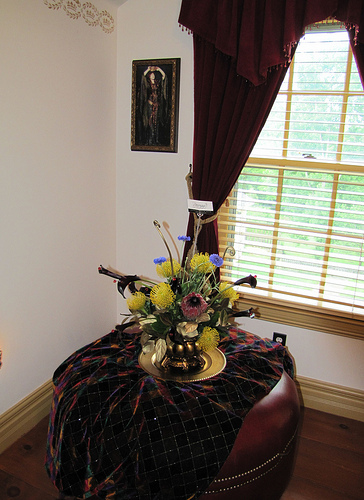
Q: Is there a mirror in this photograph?
A: No, there are no mirrors.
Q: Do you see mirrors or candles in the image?
A: No, there are no mirrors or candles.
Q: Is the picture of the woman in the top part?
A: Yes, the picture is in the top of the image.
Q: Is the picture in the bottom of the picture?
A: No, the picture is in the top of the image.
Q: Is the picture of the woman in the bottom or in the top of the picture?
A: The picture is in the top of the image.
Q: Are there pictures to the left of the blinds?
A: Yes, there is a picture to the left of the blinds.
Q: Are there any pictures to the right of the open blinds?
A: No, the picture is to the left of the blinds.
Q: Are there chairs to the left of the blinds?
A: No, there is a picture to the left of the blinds.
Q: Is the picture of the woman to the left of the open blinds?
A: Yes, the picture is to the left of the blinds.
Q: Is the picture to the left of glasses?
A: No, the picture is to the left of the blinds.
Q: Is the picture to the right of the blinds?
A: No, the picture is to the left of the blinds.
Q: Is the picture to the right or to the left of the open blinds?
A: The picture is to the left of the blinds.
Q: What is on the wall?
A: The picture is on the wall.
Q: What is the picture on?
A: The picture is on the wall.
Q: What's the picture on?
A: The picture is on the wall.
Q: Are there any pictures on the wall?
A: Yes, there is a picture on the wall.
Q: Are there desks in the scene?
A: No, there are no desks.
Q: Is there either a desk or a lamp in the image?
A: No, there are no desks or lamps.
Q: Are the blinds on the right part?
A: Yes, the blinds are on the right of the image.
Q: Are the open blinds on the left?
A: No, the blinds are on the right of the image.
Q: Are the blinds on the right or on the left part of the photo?
A: The blinds are on the right of the image.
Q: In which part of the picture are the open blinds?
A: The blinds are on the right of the image.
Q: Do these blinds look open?
A: Yes, the blinds are open.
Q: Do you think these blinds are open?
A: Yes, the blinds are open.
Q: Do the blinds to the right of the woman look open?
A: Yes, the blinds are open.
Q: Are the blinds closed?
A: No, the blinds are open.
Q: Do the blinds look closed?
A: No, the blinds are open.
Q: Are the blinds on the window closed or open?
A: The blinds are open.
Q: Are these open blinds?
A: Yes, these are open blinds.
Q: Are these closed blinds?
A: No, these are open blinds.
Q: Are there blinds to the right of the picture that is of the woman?
A: Yes, there are blinds to the right of the picture.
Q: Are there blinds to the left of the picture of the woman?
A: No, the blinds are to the right of the picture.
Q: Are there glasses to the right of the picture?
A: No, there are blinds to the right of the picture.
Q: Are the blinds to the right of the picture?
A: Yes, the blinds are to the right of the picture.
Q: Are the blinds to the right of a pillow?
A: No, the blinds are to the right of the picture.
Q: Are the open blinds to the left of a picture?
A: No, the blinds are to the right of a picture.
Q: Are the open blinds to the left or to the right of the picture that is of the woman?
A: The blinds are to the right of the picture.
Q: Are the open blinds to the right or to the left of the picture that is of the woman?
A: The blinds are to the right of the picture.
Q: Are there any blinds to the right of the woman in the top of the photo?
A: Yes, there are blinds to the right of the woman.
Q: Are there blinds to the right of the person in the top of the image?
A: Yes, there are blinds to the right of the woman.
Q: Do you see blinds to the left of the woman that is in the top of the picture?
A: No, the blinds are to the right of the woman.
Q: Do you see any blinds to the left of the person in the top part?
A: No, the blinds are to the right of the woman.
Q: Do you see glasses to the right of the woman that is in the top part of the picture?
A: No, there are blinds to the right of the woman.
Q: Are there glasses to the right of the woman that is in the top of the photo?
A: No, there are blinds to the right of the woman.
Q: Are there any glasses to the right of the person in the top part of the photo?
A: No, there are blinds to the right of the woman.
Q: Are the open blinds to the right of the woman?
A: Yes, the blinds are to the right of the woman.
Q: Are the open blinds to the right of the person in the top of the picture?
A: Yes, the blinds are to the right of the woman.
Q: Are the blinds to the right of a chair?
A: No, the blinds are to the right of the woman.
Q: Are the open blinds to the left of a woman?
A: No, the blinds are to the right of a woman.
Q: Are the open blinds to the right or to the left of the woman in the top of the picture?
A: The blinds are to the right of the woman.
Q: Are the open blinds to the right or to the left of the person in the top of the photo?
A: The blinds are to the right of the woman.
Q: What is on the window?
A: The blinds are on the window.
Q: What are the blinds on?
A: The blinds are on the window.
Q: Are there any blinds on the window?
A: Yes, there are blinds on the window.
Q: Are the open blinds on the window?
A: Yes, the blinds are on the window.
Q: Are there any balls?
A: No, there are no balls.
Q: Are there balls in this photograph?
A: No, there are no balls.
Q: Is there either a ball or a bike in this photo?
A: No, there are no balls or bikes.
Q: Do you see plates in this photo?
A: Yes, there is a plate.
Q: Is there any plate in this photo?
A: Yes, there is a plate.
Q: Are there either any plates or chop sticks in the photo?
A: Yes, there is a plate.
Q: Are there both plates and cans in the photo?
A: No, there is a plate but no cans.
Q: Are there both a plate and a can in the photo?
A: No, there is a plate but no cans.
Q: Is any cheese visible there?
A: No, there is no cheese.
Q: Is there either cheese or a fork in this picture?
A: No, there are no cheese or forks.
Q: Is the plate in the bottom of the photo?
A: Yes, the plate is in the bottom of the image.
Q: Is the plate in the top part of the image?
A: No, the plate is in the bottom of the image.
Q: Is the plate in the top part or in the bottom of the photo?
A: The plate is in the bottom of the image.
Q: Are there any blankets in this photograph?
A: Yes, there is a blanket.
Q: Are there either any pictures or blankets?
A: Yes, there is a blanket.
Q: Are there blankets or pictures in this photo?
A: Yes, there is a blanket.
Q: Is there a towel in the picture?
A: No, there are no towels.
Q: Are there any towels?
A: No, there are no towels.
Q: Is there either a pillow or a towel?
A: No, there are no towels or pillows.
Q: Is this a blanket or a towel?
A: This is a blanket.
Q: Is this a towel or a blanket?
A: This is a blanket.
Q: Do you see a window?
A: Yes, there is a window.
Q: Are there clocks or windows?
A: Yes, there is a window.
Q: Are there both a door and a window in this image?
A: No, there is a window but no doors.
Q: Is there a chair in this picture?
A: No, there are no chairs.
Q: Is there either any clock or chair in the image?
A: No, there are no chairs or clocks.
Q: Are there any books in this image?
A: No, there are no books.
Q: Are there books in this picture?
A: No, there are no books.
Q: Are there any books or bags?
A: No, there are no books or bags.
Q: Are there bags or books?
A: No, there are no books or bags.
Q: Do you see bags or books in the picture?
A: No, there are no books or bags.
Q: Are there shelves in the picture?
A: No, there are no shelves.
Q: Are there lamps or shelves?
A: No, there are no shelves or lamps.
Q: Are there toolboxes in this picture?
A: No, there are no toolboxes.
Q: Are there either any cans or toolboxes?
A: No, there are no toolboxes or cans.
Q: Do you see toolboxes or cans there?
A: No, there are no toolboxes or cans.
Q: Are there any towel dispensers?
A: No, there are no towel dispensers.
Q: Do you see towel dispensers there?
A: No, there are no towel dispensers.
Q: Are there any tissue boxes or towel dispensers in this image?
A: No, there are no towel dispensers or tissue boxes.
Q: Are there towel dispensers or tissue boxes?
A: No, there are no towel dispensers or tissue boxes.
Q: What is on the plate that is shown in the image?
A: The vase is on the plate.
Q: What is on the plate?
A: The vase is on the plate.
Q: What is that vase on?
A: The vase is on the plate.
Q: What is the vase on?
A: The vase is on the plate.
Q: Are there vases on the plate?
A: Yes, there is a vase on the plate.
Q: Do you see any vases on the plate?
A: Yes, there is a vase on the plate.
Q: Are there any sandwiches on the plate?
A: No, there is a vase on the plate.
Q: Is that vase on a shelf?
A: No, the vase is on the plate.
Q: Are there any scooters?
A: No, there are no scooters.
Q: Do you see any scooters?
A: No, there are no scooters.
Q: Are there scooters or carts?
A: No, there are no scooters or carts.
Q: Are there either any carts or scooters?
A: No, there are no scooters or carts.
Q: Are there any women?
A: Yes, there is a woman.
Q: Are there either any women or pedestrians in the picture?
A: Yes, there is a woman.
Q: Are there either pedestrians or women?
A: Yes, there is a woman.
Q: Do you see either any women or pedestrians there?
A: Yes, there is a woman.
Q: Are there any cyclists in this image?
A: No, there are no cyclists.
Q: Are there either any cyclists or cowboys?
A: No, there are no cyclists or cowboys.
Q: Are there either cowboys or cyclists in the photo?
A: No, there are no cyclists or cowboys.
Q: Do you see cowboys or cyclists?
A: No, there are no cyclists or cowboys.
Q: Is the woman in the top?
A: Yes, the woman is in the top of the image.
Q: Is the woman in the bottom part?
A: No, the woman is in the top of the image.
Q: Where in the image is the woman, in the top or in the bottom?
A: The woman is in the top of the image.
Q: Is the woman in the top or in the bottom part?
A: The woman is in the top of the image.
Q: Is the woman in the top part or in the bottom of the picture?
A: The woman is in the top of the image.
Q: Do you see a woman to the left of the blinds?
A: Yes, there is a woman to the left of the blinds.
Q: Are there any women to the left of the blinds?
A: Yes, there is a woman to the left of the blinds.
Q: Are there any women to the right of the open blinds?
A: No, the woman is to the left of the blinds.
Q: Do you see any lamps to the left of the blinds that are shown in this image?
A: No, there is a woman to the left of the blinds.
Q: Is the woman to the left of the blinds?
A: Yes, the woman is to the left of the blinds.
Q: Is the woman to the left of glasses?
A: No, the woman is to the left of the blinds.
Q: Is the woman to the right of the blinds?
A: No, the woman is to the left of the blinds.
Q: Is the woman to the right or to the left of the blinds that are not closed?
A: The woman is to the left of the blinds.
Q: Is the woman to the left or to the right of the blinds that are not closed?
A: The woman is to the left of the blinds.